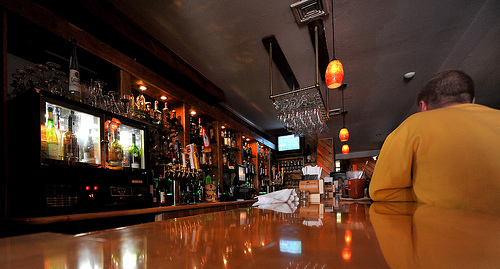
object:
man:
[368, 68, 499, 209]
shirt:
[368, 102, 499, 212]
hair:
[415, 67, 476, 107]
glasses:
[303, 96, 319, 116]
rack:
[262, 18, 330, 125]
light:
[325, 60, 349, 90]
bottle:
[66, 36, 82, 100]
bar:
[1, 194, 389, 269]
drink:
[347, 160, 368, 199]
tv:
[275, 134, 302, 151]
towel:
[252, 187, 300, 210]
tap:
[174, 140, 182, 164]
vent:
[290, 0, 330, 27]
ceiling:
[106, 1, 499, 160]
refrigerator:
[1, 87, 155, 217]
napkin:
[341, 196, 371, 201]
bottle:
[129, 134, 141, 169]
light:
[139, 85, 148, 92]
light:
[336, 127, 351, 142]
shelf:
[278, 155, 305, 174]